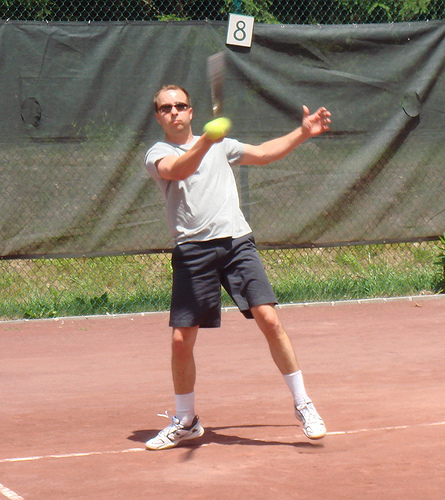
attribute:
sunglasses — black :
[161, 103, 220, 120]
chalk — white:
[2, 290, 442, 498]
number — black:
[228, 15, 253, 51]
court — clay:
[0, 289, 441, 498]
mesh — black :
[1, 19, 444, 258]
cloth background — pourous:
[1, 19, 444, 259]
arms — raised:
[144, 97, 347, 180]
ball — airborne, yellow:
[187, 116, 252, 154]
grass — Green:
[269, 242, 440, 299]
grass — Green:
[0, 259, 165, 317]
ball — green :
[165, 96, 281, 165]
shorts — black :
[168, 230, 278, 327]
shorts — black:
[159, 232, 293, 330]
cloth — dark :
[0, 17, 443, 255]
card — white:
[224, 12, 253, 50]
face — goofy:
[155, 91, 190, 133]